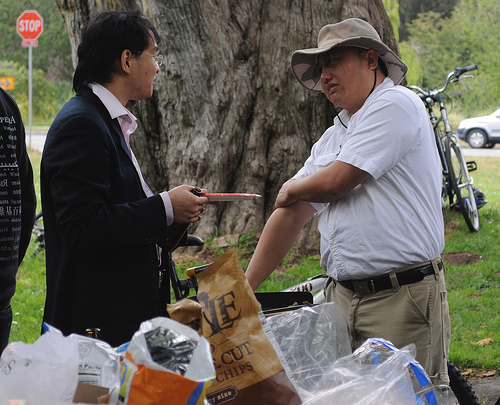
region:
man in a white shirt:
[239, 16, 456, 390]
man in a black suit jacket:
[37, 0, 210, 353]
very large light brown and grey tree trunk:
[51, 2, 424, 264]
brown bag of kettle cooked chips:
[183, 239, 320, 404]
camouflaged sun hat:
[282, 11, 410, 102]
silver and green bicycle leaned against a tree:
[407, 58, 497, 245]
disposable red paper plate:
[197, 184, 264, 215]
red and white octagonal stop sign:
[16, 5, 48, 42]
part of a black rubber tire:
[437, 348, 487, 403]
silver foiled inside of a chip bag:
[136, 322, 196, 374]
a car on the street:
[455, 105, 497, 145]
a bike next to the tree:
[423, 80, 490, 232]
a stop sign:
[10, 6, 45, 136]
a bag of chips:
[190, 260, 275, 400]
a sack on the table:
[275, 306, 396, 396]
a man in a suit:
[47, 16, 197, 336]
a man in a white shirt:
[285, 26, 497, 382]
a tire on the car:
[467, 127, 479, 147]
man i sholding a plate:
[53, 7, 265, 250]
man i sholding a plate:
[39, 21, 253, 285]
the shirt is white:
[280, 121, 443, 272]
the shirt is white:
[290, 97, 444, 284]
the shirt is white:
[275, 92, 447, 272]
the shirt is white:
[274, 85, 417, 282]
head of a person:
[290, 13, 404, 111]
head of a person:
[69, 9, 186, 110]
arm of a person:
[302, 112, 467, 233]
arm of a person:
[239, 165, 356, 290]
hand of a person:
[172, 176, 216, 237]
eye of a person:
[302, 46, 360, 76]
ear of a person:
[357, 35, 392, 79]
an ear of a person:
[357, 39, 401, 81]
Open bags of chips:
[106, 253, 298, 403]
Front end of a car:
[459, 100, 499, 151]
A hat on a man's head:
[288, 19, 410, 88]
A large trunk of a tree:
[55, 3, 408, 253]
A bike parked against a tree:
[417, 60, 482, 235]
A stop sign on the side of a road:
[14, 9, 44, 49]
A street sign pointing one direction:
[0, 75, 15, 89]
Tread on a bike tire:
[449, 366, 477, 403]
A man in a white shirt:
[236, 18, 456, 391]